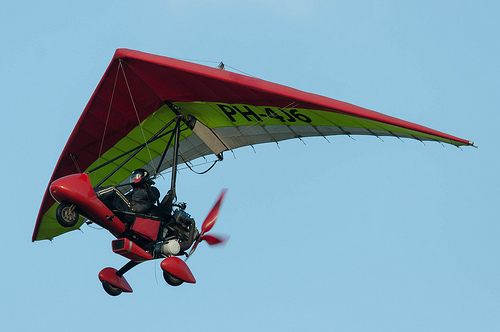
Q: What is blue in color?
A: The sky.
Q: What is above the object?
A: The sky.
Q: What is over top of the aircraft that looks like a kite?
A: Parasail.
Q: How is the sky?
A: Clear.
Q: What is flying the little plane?
A: Pilot.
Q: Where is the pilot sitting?
A: Cockpit.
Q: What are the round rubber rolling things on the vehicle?
A: Wheels.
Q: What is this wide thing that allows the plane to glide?
A: Wing.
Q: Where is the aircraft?
A: The sky.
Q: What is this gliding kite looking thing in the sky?
A: Hang glider.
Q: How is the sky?
A: Clear.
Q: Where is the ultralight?
A: In the sky.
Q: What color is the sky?
A: Blue.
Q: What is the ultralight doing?
A: Flying.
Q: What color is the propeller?
A: Red.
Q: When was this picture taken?
A: Daytime.